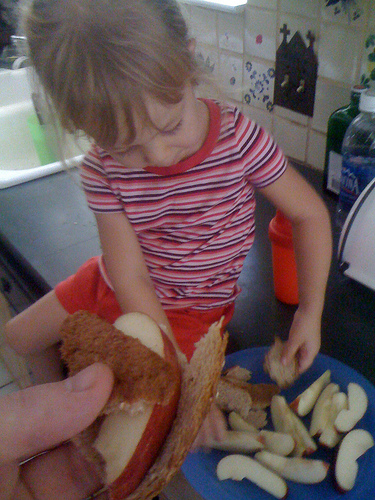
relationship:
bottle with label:
[334, 85, 374, 245] [336, 156, 363, 196]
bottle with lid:
[334, 85, 374, 245] [356, 90, 363, 101]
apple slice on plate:
[334, 382, 369, 424] [176, 334, 373, 499]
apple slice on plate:
[332, 428, 371, 488] [176, 334, 373, 499]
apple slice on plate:
[289, 369, 338, 413] [176, 334, 373, 499]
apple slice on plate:
[274, 384, 306, 452] [176, 334, 373, 499]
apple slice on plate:
[259, 446, 330, 485] [176, 334, 373, 499]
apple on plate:
[254, 399, 346, 464] [197, 344, 373, 488]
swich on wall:
[272, 61, 314, 116] [192, 1, 363, 164]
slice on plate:
[213, 451, 289, 496] [325, 370, 349, 384]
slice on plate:
[340, 424, 363, 496] [198, 348, 363, 493]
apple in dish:
[268, 392, 318, 462] [180, 335, 372, 495]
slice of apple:
[213, 451, 289, 496] [212, 416, 329, 498]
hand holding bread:
[283, 306, 323, 376] [258, 332, 299, 389]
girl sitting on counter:
[5, 0, 352, 377] [2, 130, 373, 499]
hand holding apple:
[130, 332, 200, 392] [93, 310, 178, 499]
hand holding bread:
[130, 332, 200, 392] [56, 310, 231, 498]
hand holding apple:
[0, 363, 132, 499] [93, 310, 178, 499]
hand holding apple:
[0, 363, 132, 499] [220, 427, 262, 450]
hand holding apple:
[0, 363, 132, 499] [217, 453, 290, 497]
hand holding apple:
[0, 363, 132, 499] [333, 426, 372, 495]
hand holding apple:
[0, 363, 132, 499] [269, 395, 314, 453]